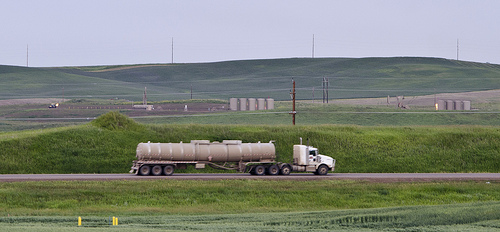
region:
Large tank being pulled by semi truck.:
[128, 139, 337, 177]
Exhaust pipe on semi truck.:
[295, 135, 305, 142]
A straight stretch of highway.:
[4, 172, 499, 183]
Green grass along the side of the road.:
[2, 181, 497, 230]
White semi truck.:
[282, 140, 341, 175]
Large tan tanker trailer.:
[130, 137, 290, 177]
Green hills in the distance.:
[2, 56, 499, 96]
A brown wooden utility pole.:
[287, 75, 300, 122]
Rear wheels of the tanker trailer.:
[139, 163, 172, 175]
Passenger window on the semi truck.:
[308, 148, 314, 157]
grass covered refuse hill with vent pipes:
[7, 29, 487, 86]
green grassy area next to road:
[12, 179, 477, 226]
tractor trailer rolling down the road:
[125, 134, 339, 178]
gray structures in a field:
[422, 95, 476, 112]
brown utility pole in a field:
[275, 74, 306, 129]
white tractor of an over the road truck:
[284, 136, 339, 178]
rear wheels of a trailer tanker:
[133, 159, 180, 179]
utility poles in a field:
[317, 72, 339, 105]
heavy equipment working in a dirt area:
[42, 97, 65, 112]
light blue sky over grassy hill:
[54, 3, 471, 58]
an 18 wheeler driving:
[53, 71, 410, 229]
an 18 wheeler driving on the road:
[78, 78, 370, 218]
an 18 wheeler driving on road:
[86, 65, 383, 230]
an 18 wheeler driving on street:
[130, 81, 374, 191]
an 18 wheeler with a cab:
[107, 51, 364, 189]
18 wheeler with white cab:
[93, 90, 412, 205]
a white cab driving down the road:
[126, 107, 396, 230]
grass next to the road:
[67, 73, 399, 226]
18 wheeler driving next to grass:
[82, 97, 383, 201]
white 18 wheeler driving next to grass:
[83, 86, 396, 205]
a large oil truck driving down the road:
[121, 134, 337, 177]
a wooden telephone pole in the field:
[288, 78, 299, 124]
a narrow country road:
[1, 170, 499, 176]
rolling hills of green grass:
[0, 56, 497, 96]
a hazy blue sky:
[1, 1, 499, 66]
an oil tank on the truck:
[133, 136, 277, 162]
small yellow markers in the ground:
[73, 214, 118, 226]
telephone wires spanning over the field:
[1, 77, 499, 123]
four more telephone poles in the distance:
[18, 33, 473, 68]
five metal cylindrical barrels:
[228, 94, 277, 112]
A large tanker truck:
[120, 128, 342, 180]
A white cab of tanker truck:
[293, 138, 337, 178]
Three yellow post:
[68, 204, 128, 229]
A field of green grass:
[158, 183, 265, 217]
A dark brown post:
[278, 70, 305, 132]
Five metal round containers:
[223, 93, 279, 112]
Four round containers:
[429, 93, 476, 118]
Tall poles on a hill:
[304, 25, 324, 58]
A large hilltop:
[123, 40, 487, 97]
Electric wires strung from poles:
[298, 67, 472, 117]